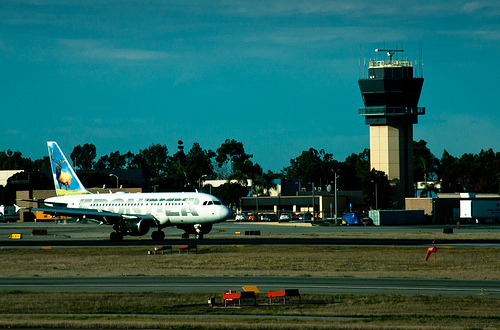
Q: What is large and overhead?
A: Airplane tower.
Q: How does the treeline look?
A: It is green.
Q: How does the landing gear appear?
A: It is down.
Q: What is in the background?
A: Airport tower base.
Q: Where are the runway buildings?
A: Behind the scene.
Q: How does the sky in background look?
A: Cloudless sky.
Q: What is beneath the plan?
A: Grassy ground.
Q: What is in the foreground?
A: Grassy area for airport.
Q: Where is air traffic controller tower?
A: At airport.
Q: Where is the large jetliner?
A: At airport.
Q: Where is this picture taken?
A: Airport.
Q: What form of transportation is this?
A: Airplane.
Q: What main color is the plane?
A: White.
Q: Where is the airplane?
A: On the runway.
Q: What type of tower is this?
A: Air traffic control tower.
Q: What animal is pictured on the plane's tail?
A: Deer.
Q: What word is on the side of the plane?
A: Frontier.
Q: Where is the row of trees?
A: Behind airport.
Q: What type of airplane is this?
A: Passenger plane.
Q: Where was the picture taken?
A: At the airport.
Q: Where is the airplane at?
A: At the airport.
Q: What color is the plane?
A: White.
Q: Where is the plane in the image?
A: On the left.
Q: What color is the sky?
A: Blue.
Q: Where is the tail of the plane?
A: In the back.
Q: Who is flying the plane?
A: A pilot.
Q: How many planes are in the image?
A: One.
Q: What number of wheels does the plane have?
A: Three.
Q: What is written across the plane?
A: Frontier.